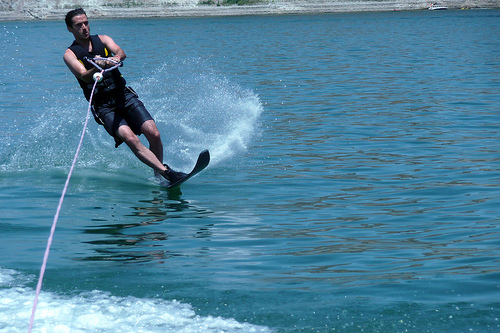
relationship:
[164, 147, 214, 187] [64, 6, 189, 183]
water skiis on a man